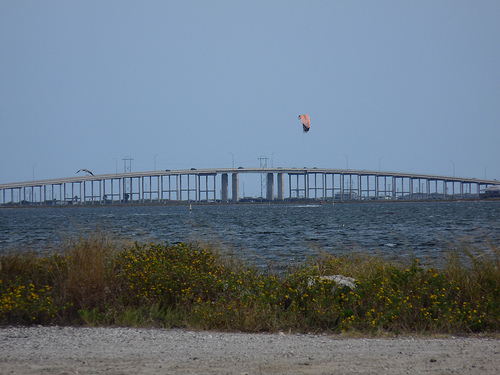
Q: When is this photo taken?
A: Daytime.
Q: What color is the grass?
A: Green.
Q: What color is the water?
A: Blue.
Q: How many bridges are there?
A: One.